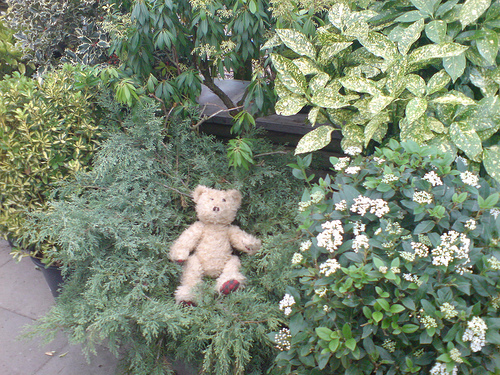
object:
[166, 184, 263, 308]
bear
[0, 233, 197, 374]
ground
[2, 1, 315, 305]
bushes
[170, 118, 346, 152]
wall